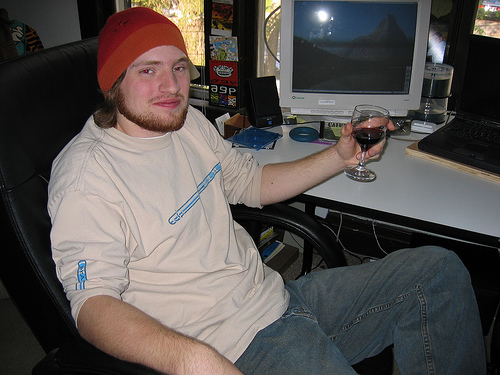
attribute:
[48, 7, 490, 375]
man — sitting, young, relaxing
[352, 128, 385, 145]
wine — red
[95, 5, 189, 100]
hat — red, orange, knitted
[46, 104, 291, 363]
shirt — white, long sleeve, beige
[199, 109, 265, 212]
sleeve — pushed up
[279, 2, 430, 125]
computer monitor — white, large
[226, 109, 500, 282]
table — white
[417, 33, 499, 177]
laptop computer — black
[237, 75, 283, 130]
speaker — black, small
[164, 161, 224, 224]
design — blue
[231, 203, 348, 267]
arm rest — black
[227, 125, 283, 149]
cd case — blue, plastic, small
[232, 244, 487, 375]
jeans — blue, dirty, faded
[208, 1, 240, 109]
stickers — colorful